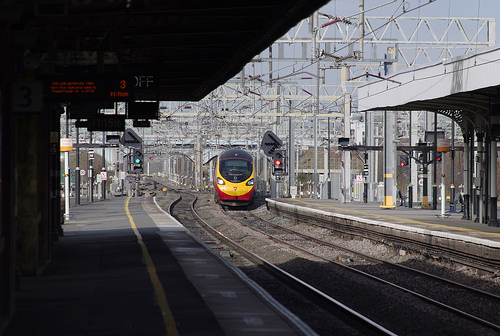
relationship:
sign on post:
[56, 136, 86, 156] [62, 145, 75, 225]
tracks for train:
[251, 209, 356, 281] [209, 148, 251, 205]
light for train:
[265, 144, 288, 169] [209, 148, 251, 205]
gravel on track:
[307, 227, 335, 260] [163, 188, 213, 234]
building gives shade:
[17, 20, 213, 102] [64, 237, 182, 332]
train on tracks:
[209, 148, 251, 205] [251, 209, 356, 281]